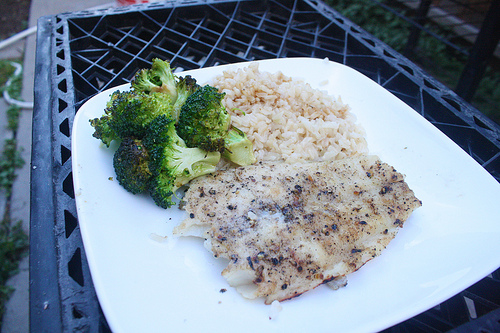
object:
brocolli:
[112, 122, 203, 204]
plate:
[97, 205, 209, 328]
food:
[89, 55, 421, 305]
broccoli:
[89, 54, 254, 204]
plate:
[66, 69, 496, 329]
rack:
[115, 15, 270, 54]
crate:
[31, 0, 496, 332]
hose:
[0, 22, 36, 113]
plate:
[80, 167, 210, 332]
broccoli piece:
[112, 117, 219, 204]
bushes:
[423, 31, 453, 59]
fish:
[205, 106, 407, 253]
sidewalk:
[1, 0, 83, 330]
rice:
[212, 56, 362, 158]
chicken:
[178, 137, 429, 307]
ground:
[0, 179, 33, 270]